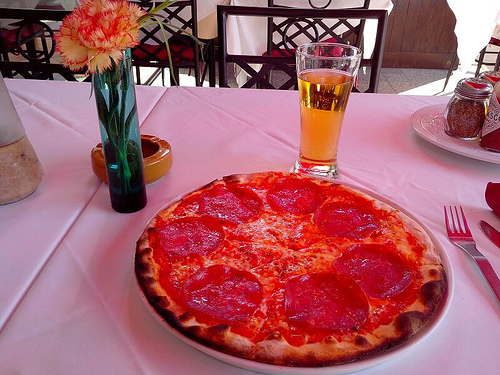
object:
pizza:
[133, 170, 447, 369]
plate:
[131, 169, 456, 374]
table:
[0, 74, 499, 375]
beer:
[297, 67, 353, 166]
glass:
[293, 42, 366, 180]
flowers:
[54, 0, 148, 77]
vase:
[90, 42, 149, 215]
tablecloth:
[0, 77, 500, 375]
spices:
[444, 77, 498, 139]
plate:
[407, 94, 499, 166]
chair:
[213, 2, 390, 94]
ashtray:
[90, 133, 175, 186]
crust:
[133, 169, 449, 370]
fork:
[441, 205, 500, 300]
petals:
[54, 0, 148, 77]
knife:
[478, 219, 499, 248]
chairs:
[90, 1, 218, 89]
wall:
[358, 0, 460, 72]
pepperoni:
[154, 176, 418, 334]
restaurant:
[0, 1, 499, 374]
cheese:
[144, 173, 442, 367]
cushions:
[123, 43, 195, 62]